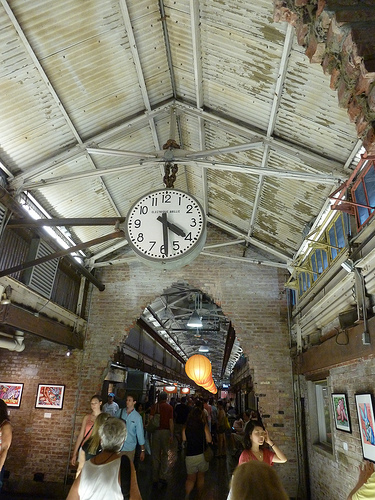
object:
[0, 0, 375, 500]
station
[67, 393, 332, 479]
else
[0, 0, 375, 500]
looks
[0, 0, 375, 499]
building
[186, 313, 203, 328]
fluorescent lights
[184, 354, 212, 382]
ones